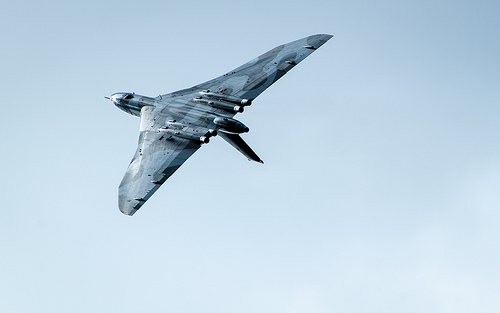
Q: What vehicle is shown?
A: Airplane.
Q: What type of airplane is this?
A: Jet.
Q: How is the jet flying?
A: Upside down.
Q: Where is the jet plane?
A: Sky.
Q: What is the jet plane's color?
A: Gray.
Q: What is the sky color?
A: Blue.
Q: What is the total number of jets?
A: 1.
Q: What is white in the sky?
A: Clouds.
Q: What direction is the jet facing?
A: Left.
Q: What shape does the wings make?
A: Triangle.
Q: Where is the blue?
A: In the sky.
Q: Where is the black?
A: On jet.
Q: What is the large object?
A: A jet.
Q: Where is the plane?
A: In the sky.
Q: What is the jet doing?
A: Flying.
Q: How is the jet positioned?
A: It is upside down.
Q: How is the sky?
A: Clear and light blue.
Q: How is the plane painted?
A: In blue camo colors.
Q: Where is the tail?
A: Under the plane.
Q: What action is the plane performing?
A: It is turning.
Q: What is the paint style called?
A: Camouflage.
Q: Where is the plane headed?
A: To the left.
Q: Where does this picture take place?
A: In the sky.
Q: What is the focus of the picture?
A: An airplane.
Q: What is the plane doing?
A: It is flying.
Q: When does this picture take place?
A: In the daytime.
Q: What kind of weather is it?
A: Clear.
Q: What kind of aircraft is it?
A: Fighter jet.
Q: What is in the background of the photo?
A: The sky.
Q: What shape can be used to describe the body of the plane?
A: A triangle.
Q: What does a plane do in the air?
A: It flies.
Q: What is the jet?
A: Flying.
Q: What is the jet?
A: Flying.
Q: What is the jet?
A: Flying.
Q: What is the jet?
A: Flying.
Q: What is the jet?
A: Flying.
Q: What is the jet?
A: Flying.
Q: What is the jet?
A: Flying.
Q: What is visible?
A: The jet plane.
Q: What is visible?
A: The jet plane.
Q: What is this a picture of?
A: An aircraft.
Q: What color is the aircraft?
A: Blue.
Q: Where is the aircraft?
A: The sky.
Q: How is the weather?
A: Sunny.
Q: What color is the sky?
A: Light blue.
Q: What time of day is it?
A: Daytime.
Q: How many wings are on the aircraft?
A: 2.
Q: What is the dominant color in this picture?
A: Blue.